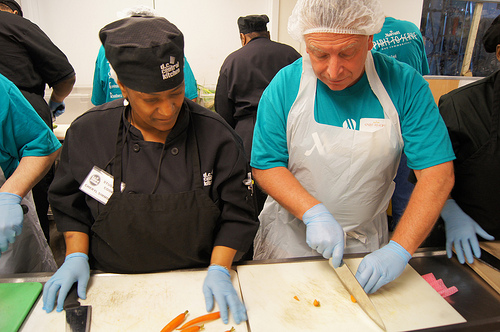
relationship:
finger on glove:
[202, 286, 214, 313] [202, 261, 247, 324]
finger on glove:
[202, 286, 214, 313] [36, 250, 96, 307]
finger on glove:
[202, 286, 214, 313] [299, 200, 349, 266]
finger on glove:
[443, 239, 455, 259] [352, 239, 412, 294]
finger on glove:
[452, 239, 466, 263] [438, 198, 493, 261]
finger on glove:
[443, 239, 455, 259] [428, 193, 497, 268]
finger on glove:
[46, 280, 56, 310] [41, 250, 92, 312]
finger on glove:
[208, 277, 213, 307] [201, 263, 250, 324]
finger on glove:
[330, 239, 349, 267] [299, 200, 349, 266]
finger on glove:
[202, 286, 214, 313] [41, 250, 92, 312]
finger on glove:
[216, 291, 229, 323] [201, 263, 250, 324]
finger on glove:
[202, 286, 214, 313] [198, 261, 249, 326]